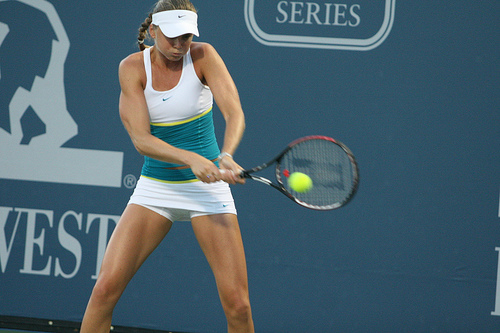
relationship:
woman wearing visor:
[72, 0, 254, 332] [146, 8, 200, 37]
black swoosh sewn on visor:
[177, 14, 185, 20] [150, 8, 200, 38]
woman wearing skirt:
[72, 0, 254, 332] [129, 172, 238, 220]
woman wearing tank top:
[72, 0, 254, 332] [142, 47, 218, 182]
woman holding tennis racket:
[72, 0, 254, 332] [202, 133, 357, 212]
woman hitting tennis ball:
[72, 0, 254, 332] [284, 170, 313, 194]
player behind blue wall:
[69, 0, 264, 332] [1, 2, 498, 328]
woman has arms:
[72, 0, 254, 332] [118, 44, 246, 183]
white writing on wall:
[2, 197, 121, 292] [0, 0, 498, 330]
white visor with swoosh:
[151, 8, 202, 36] [173, 13, 190, 21]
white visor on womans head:
[151, 8, 202, 36] [140, 0, 201, 62]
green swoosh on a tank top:
[157, 94, 175, 103] [140, 44, 223, 182]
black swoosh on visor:
[177, 14, 187, 20] [150, 8, 200, 38]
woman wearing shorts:
[72, 0, 254, 332] [129, 172, 239, 220]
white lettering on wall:
[269, 0, 368, 36] [0, 0, 498, 330]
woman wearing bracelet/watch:
[72, 0, 254, 332] [216, 150, 236, 160]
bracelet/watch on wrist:
[216, 150, 236, 160] [213, 150, 240, 161]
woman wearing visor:
[124, 139, 246, 184] [133, 49, 202, 80]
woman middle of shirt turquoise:
[72, 0, 254, 332] [132, 120, 230, 212]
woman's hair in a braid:
[125, 1, 195, 48] [112, 49, 132, 66]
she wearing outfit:
[81, 0, 359, 331] [121, 135, 234, 233]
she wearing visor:
[111, 87, 254, 275] [158, 99, 193, 122]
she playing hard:
[81, 0, 359, 331] [195, 138, 275, 200]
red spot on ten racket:
[278, 170, 290, 178] [274, 118, 364, 208]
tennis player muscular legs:
[89, 80, 245, 333] [63, 205, 250, 332]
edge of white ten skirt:
[124, 170, 264, 249] [144, 185, 191, 295]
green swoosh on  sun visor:
[157, 94, 176, 103] [163, 49, 184, 64]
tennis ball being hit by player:
[285, 164, 318, 200] [132, 115, 355, 220]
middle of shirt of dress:
[131, 105, 220, 187] [145, 105, 235, 225]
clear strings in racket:
[283, 147, 359, 204] [257, 126, 367, 195]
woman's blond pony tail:
[124, 99, 246, 160] [106, 49, 139, 73]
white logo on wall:
[253, 1, 386, 49] [18, 75, 97, 161]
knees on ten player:
[72, 298, 271, 318] [109, 160, 284, 326]